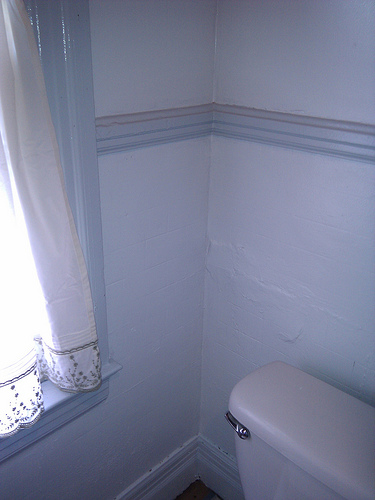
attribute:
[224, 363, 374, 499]
tank — white, ceramic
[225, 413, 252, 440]
handle — chrome plated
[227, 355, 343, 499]
tank — toilet tank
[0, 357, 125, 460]
window ledge — wooden 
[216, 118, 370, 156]
line — blue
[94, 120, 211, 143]
line — blue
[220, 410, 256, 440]
handle — metallic